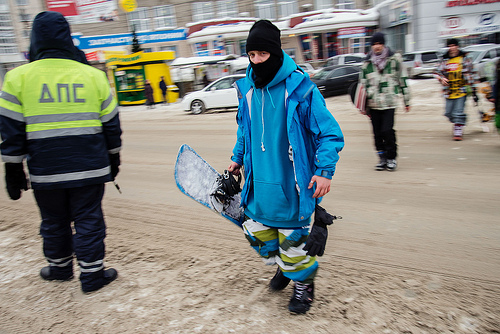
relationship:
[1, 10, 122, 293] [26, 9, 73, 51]
man wearing hat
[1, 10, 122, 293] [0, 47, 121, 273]
man turned around in clothes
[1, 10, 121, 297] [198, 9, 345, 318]
man dressed in person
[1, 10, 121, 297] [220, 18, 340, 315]
man dressed in winter clothes